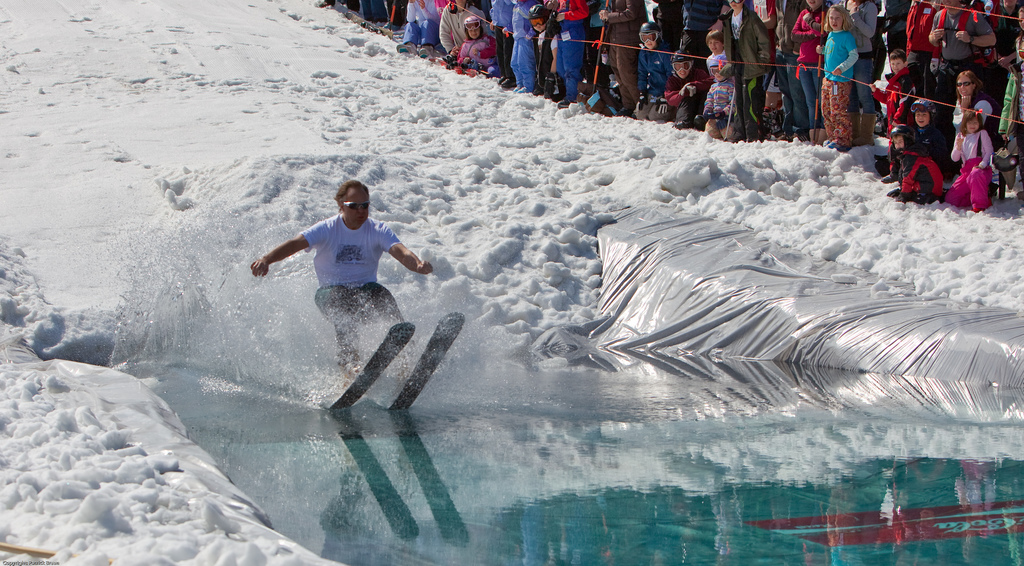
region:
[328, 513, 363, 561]
The shadow of the skier reflecting in the water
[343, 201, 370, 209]
Dark shades on the man's eyes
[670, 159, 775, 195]
Lumps of snow on the ground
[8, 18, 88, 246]
Light reflecting on the snow slope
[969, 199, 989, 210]
Knee of kid in the snow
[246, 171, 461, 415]
Man on black skis.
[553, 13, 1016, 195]
Spectators behind thin rope with orange flags.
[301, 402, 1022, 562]
Body of water frozen.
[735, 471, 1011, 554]
Red and white logo on ice.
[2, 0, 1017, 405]
Hill covered in snow.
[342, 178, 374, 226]
Protective glasses on face.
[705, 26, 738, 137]
person is in the snow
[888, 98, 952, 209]
person is in the snow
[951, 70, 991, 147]
person is in the snow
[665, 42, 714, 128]
person is in the snow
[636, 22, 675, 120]
person is in the snow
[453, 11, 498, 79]
person is in the snow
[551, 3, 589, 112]
person is in the snow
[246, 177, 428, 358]
Man wearing black pants and white shirt.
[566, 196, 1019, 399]
White plastic tarp covering something.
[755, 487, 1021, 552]
Red and white logo on the ice.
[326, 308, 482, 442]
Pair of black skis.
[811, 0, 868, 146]
Girl wearing blue shirt and red pants.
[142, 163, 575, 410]
Snow and slush in air.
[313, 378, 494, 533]
Black shadow of skis.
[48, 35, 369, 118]
Footprints in the snow.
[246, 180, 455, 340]
Man with arms out for balance.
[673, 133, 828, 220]
Clumps of dirty snow.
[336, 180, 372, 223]
person has a head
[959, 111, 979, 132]
person has a head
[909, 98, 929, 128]
person has a head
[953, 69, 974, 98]
person has a head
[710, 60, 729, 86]
person has a head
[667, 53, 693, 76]
person has a head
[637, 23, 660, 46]
person has a head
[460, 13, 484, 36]
person has a head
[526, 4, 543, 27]
person has a head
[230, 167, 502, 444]
Man in white shirt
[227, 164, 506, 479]
Man on water skis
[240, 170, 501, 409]
Man with short hair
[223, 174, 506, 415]
Man in black pants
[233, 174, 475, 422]
Man skiing on water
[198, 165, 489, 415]
Man in black pants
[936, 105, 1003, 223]
Girl in pink pants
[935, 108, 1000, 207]
Girl in pink shirt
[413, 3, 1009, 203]
People watching the man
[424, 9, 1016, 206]
Crowd watching the man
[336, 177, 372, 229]
person has a head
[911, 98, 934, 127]
person has a head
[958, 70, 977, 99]
person has a head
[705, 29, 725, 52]
person has a head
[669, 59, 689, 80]
person has a head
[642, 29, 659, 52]
person has a head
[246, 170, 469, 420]
man with skis on feet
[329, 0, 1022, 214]
crowd watching skiers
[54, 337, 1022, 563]
pool of water for skiers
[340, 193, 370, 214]
sunglasses on mans face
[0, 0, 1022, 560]
ramp covered in snow for skiers